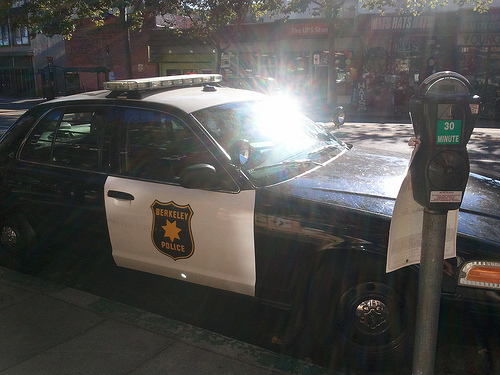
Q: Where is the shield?
A: On a white, car door.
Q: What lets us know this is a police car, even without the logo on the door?
A: The bar of lights on the hood.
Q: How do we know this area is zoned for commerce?
A: There are stores, across the street.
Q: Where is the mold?
A: On the curb, by the car.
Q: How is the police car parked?
A: It is parked parallel to the sidewalk, with the front wheel unaligned with the curb.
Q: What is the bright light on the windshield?
A: Glare from the sunlight.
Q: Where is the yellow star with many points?
A: In the center of the shield, on the police car door.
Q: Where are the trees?
A: On the sidewalk, with the stores, as well as in the distance, beyond them.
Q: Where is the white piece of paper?
A: Attached to a grey parking meter, on the front.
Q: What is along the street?
A: Stores.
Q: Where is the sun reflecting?
A: On windshield.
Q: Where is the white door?
A: On cop car.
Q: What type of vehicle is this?
A: Police car.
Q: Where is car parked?
A: On side of road.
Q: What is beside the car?
A: Parking meter.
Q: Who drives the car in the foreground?
A: A police officer.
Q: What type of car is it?
A: A police car.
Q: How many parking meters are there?
A: One.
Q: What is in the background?
A: Businesses.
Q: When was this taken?
A: During the day.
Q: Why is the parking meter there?
A: To control how long a space is occupied.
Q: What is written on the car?
A: Berkeley Police.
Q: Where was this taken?
A: California.